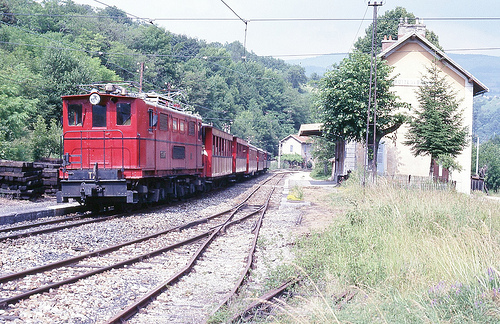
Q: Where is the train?
A: On a track.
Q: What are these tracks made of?
A: Metal.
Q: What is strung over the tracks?
A: Wiring.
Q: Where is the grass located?
A: At the right edge of the photo.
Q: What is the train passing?
A: A rural train station.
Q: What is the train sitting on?
A: Tracks.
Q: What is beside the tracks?
A: House.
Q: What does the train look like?
A: Red.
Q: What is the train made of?
A: Metal.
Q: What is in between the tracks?
A: Gravel.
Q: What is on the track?
A: Rust.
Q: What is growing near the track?
A: Grass.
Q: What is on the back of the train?
A: Windows.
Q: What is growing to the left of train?
A: Trees.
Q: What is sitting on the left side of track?
A: Railroad ties.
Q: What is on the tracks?
A: Train.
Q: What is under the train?
A: Tracks.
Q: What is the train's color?
A: Red.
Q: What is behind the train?
A: Trees.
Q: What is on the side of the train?
A: Building.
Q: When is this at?
A: During the day time.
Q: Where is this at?
A: Train station.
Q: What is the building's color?
A: White.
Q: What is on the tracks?
A: Train.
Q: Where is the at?
A: A train station.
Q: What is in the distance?
A: Mountains.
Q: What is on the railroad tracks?
A: Train.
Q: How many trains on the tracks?
A: One.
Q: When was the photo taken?
A: Daytime.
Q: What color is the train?
A: Red.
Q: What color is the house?
A: Beige.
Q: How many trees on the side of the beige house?
A: Two.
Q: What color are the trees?
A: Green.